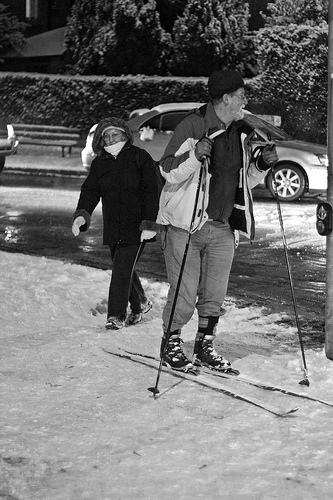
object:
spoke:
[284, 167, 291, 178]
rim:
[265, 165, 305, 204]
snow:
[0, 253, 333, 499]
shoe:
[98, 314, 126, 332]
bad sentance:
[247, 206, 279, 248]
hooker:
[266, 135, 312, 385]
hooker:
[145, 126, 213, 398]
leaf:
[307, 71, 313, 87]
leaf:
[244, 33, 279, 45]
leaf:
[253, 89, 258, 98]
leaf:
[310, 32, 325, 45]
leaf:
[264, 15, 275, 30]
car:
[80, 102, 329, 200]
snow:
[257, 307, 299, 349]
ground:
[0, 250, 332, 498]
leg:
[192, 225, 233, 374]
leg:
[159, 227, 201, 371]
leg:
[104, 241, 151, 330]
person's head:
[200, 65, 250, 126]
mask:
[102, 143, 127, 159]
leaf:
[283, 70, 305, 84]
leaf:
[306, 60, 316, 73]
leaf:
[289, 93, 296, 100]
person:
[70, 111, 164, 330]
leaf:
[287, 80, 316, 145]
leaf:
[279, 100, 307, 110]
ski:
[100, 345, 333, 416]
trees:
[168, 0, 244, 77]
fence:
[0, 68, 294, 142]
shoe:
[158, 321, 200, 374]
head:
[90, 115, 137, 154]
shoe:
[124, 300, 157, 326]